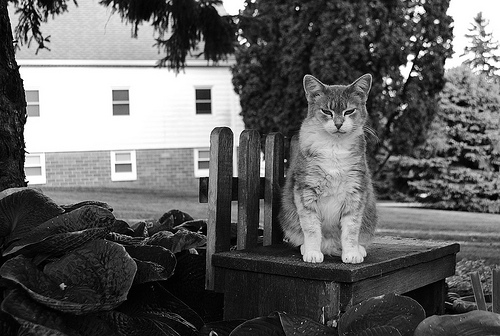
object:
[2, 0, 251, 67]
roof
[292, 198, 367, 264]
limbs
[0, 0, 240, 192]
tree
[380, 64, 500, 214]
tree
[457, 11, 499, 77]
tree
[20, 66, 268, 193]
wall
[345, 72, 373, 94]
ears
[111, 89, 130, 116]
window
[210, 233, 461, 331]
table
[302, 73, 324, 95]
ear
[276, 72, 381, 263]
car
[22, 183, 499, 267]
ground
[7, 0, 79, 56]
branches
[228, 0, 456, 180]
tree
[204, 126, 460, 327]
chair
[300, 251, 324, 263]
paws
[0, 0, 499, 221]
background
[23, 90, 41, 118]
window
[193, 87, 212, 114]
window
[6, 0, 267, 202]
building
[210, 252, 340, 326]
wood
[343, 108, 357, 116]
eyes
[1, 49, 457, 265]
camera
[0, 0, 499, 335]
photo